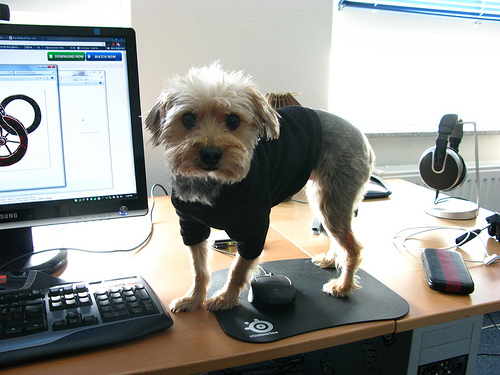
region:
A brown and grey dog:
[133, 61, 389, 332]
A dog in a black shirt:
[124, 65, 404, 334]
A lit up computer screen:
[1, 27, 158, 235]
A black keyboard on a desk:
[4, 260, 218, 367]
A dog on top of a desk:
[118, 57, 438, 323]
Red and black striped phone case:
[392, 224, 487, 309]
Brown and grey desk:
[39, 122, 481, 359]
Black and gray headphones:
[399, 93, 493, 232]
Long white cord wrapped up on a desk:
[361, 186, 496, 280]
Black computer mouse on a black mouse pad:
[146, 222, 415, 324]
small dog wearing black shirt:
[139, 73, 378, 313]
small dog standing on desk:
[138, 59, 376, 314]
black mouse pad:
[188, 256, 412, 347]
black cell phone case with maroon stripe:
[417, 241, 477, 297]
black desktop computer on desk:
[2, 60, 172, 370]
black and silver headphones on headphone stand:
[411, 108, 487, 222]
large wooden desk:
[0, 175, 499, 374]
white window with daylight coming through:
[328, 61, 499, 163]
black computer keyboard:
[0, 261, 174, 371]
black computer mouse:
[249, 268, 299, 315]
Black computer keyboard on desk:
[0, 269, 184, 370]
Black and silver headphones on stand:
[411, 109, 489, 224]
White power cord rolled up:
[391, 216, 498, 266]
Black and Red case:
[408, 237, 478, 302]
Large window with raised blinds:
[314, 2, 499, 153]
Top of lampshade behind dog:
[255, 80, 320, 116]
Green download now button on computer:
[36, 43, 88, 66]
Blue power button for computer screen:
[110, 202, 135, 222]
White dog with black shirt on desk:
[138, 58, 379, 313]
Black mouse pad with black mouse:
[188, 247, 418, 344]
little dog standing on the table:
[139, 54, 396, 350]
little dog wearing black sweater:
[139, 58, 451, 348]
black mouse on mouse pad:
[253, 242, 320, 333]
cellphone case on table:
[410, 222, 498, 319]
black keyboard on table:
[0, 270, 187, 367]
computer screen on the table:
[0, 13, 177, 254]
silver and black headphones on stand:
[412, 97, 498, 233]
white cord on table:
[386, 195, 498, 293]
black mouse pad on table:
[184, 247, 425, 343]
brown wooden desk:
[0, 167, 499, 373]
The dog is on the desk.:
[151, 78, 391, 310]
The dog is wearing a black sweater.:
[169, 68, 314, 220]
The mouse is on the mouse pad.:
[248, 261, 310, 316]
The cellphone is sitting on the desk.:
[416, 228, 491, 314]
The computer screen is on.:
[6, 63, 148, 233]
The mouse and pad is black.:
[207, 260, 420, 325]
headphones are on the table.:
[423, 103, 466, 211]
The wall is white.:
[181, 9, 336, 72]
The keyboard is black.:
[7, 272, 202, 339]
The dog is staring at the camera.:
[165, 75, 316, 214]